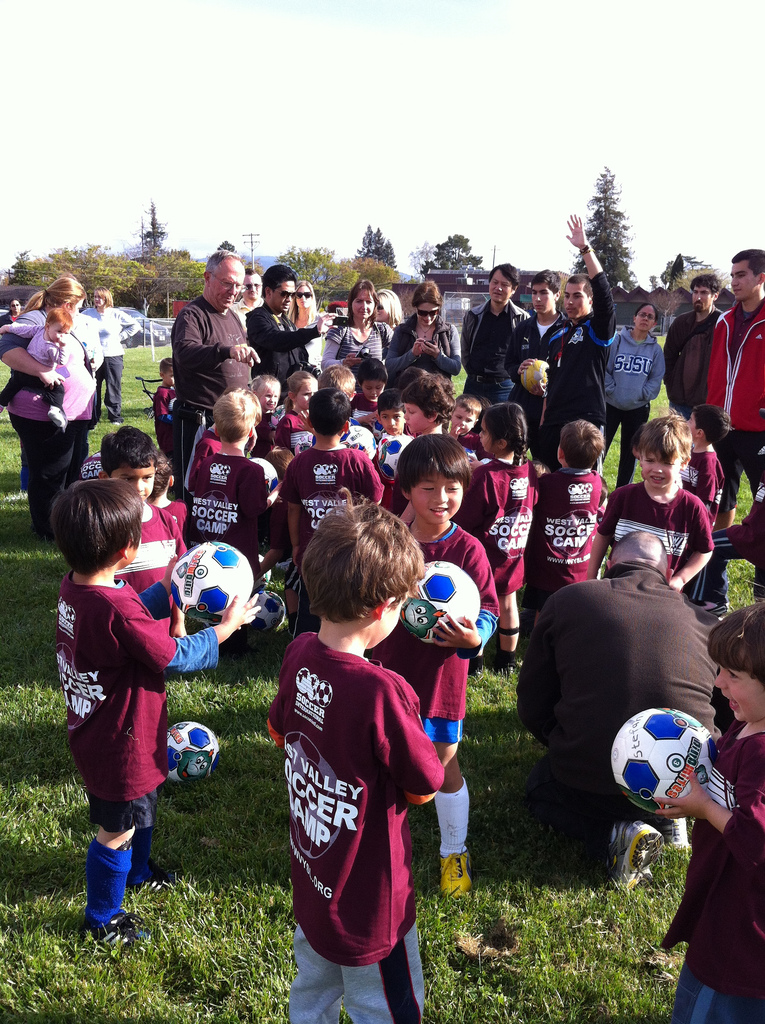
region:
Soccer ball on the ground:
[161, 715, 222, 787]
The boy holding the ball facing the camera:
[392, 432, 499, 885]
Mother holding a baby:
[0, 274, 106, 541]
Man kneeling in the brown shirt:
[513, 528, 729, 893]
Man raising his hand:
[530, 213, 615, 426]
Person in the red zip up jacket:
[706, 249, 762, 534]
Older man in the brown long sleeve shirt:
[166, 246, 262, 479]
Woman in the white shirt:
[82, 284, 143, 434]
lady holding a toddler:
[17, 246, 138, 530]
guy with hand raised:
[499, 202, 649, 459]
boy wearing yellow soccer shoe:
[368, 424, 498, 909]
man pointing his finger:
[169, 227, 309, 502]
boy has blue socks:
[22, 463, 218, 950]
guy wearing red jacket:
[693, 237, 761, 505]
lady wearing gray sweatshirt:
[597, 289, 709, 483]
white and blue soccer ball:
[593, 696, 711, 816]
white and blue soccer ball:
[396, 546, 476, 653]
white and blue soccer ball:
[173, 536, 266, 629]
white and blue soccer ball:
[163, 722, 225, 795]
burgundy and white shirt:
[267, 630, 440, 970]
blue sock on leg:
[80, 833, 135, 947]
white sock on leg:
[431, 769, 473, 862]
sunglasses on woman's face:
[413, 303, 445, 322]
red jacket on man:
[705, 306, 764, 432]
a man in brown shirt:
[479, 518, 727, 914]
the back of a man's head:
[580, 527, 699, 587]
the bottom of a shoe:
[619, 817, 661, 898]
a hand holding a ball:
[607, 703, 722, 817]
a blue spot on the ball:
[620, 752, 661, 805]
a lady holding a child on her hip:
[0, 261, 103, 550]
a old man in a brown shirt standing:
[168, 237, 265, 418]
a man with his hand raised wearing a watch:
[508, 179, 628, 428]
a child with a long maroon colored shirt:
[41, 476, 258, 949]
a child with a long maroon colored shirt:
[266, 495, 450, 1022]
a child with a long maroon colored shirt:
[361, 433, 497, 756]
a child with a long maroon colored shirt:
[187, 388, 268, 583]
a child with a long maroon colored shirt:
[289, 383, 375, 517]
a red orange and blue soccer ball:
[159, 718, 220, 775]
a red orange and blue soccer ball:
[602, 706, 716, 814]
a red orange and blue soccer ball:
[392, 559, 487, 644]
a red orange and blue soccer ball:
[249, 455, 280, 487]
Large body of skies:
[305, 155, 473, 215]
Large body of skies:
[4, 17, 202, 172]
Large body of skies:
[331, 19, 599, 143]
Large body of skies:
[496, 27, 705, 136]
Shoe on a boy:
[435, 847, 475, 903]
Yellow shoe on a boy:
[436, 845, 477, 899]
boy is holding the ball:
[49, 471, 257, 954]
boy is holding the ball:
[608, 603, 760, 1017]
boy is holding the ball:
[363, 430, 497, 892]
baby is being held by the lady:
[0, 310, 68, 426]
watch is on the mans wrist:
[577, 245, 591, 252]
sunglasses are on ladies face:
[275, 285, 296, 295]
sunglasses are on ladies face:
[293, 286, 311, 298]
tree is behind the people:
[566, 165, 647, 289]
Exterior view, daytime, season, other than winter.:
[4, 247, 764, 1015]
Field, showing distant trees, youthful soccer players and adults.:
[7, 205, 752, 1021]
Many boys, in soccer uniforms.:
[66, 365, 762, 1005]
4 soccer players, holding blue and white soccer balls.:
[76, 451, 764, 985]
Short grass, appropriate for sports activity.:
[17, 929, 250, 1014]